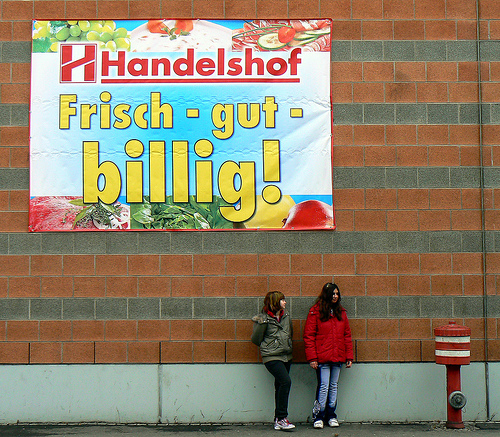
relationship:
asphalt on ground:
[10, 418, 498, 437] [208, 423, 237, 436]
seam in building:
[472, 0, 486, 374] [0, 2, 498, 379]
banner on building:
[24, 12, 342, 235] [0, 2, 498, 379]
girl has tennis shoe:
[249, 289, 302, 434] [273, 412, 297, 437]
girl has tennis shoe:
[308, 280, 356, 426] [311, 415, 340, 430]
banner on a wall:
[24, 12, 342, 235] [337, 26, 354, 226]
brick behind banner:
[22, 0, 339, 22] [24, 12, 342, 235]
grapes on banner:
[38, 20, 138, 60] [24, 12, 342, 235]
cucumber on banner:
[261, 26, 323, 49] [24, 12, 342, 235]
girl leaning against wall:
[249, 289, 302, 434] [337, 26, 354, 226]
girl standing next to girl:
[249, 289, 302, 434] [308, 280, 356, 426]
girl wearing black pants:
[249, 289, 302, 434] [261, 359, 296, 428]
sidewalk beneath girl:
[267, 429, 298, 437] [249, 289, 302, 434]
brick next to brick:
[358, 20, 392, 37] [395, 19, 424, 38]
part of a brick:
[381, 27, 391, 38] [22, 0, 339, 22]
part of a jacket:
[271, 331, 282, 343] [248, 313, 301, 368]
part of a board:
[310, 24, 324, 46] [24, 12, 342, 235]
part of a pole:
[477, 137, 484, 160] [475, 80, 486, 197]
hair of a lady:
[322, 300, 327, 318] [308, 280, 356, 426]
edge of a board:
[315, 20, 331, 36] [24, 12, 342, 235]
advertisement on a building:
[24, 12, 342, 235] [0, 2, 498, 379]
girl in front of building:
[249, 290, 296, 431] [0, 2, 498, 379]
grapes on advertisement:
[38, 20, 138, 60] [24, 12, 342, 235]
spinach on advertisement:
[149, 196, 235, 233] [24, 12, 342, 235]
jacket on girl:
[248, 313, 301, 368] [249, 289, 302, 434]